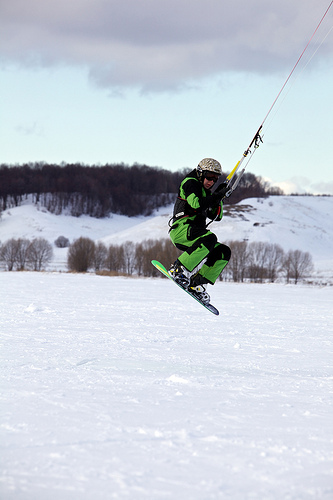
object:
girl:
[168, 158, 232, 305]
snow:
[81, 311, 333, 499]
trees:
[59, 161, 123, 212]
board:
[151, 258, 220, 316]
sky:
[0, 0, 333, 104]